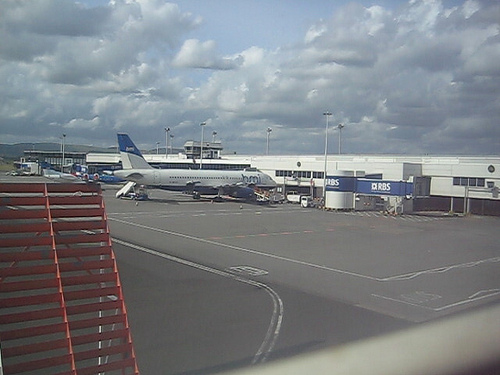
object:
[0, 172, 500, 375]
runway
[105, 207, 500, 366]
lines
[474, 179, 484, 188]
window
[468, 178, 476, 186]
window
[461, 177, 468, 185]
window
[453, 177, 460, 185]
window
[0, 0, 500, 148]
dark clouds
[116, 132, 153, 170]
tail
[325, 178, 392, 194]
logo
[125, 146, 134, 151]
logo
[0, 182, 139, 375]
red steel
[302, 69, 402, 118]
gray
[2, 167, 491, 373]
walkway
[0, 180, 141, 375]
object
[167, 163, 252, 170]
windows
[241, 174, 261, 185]
blue logo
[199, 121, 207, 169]
lightposts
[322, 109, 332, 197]
lightposts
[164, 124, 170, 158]
lightposts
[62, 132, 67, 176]
lightposts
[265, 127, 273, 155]
lightposts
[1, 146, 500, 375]
tarmac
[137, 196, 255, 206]
shadow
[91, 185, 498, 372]
ground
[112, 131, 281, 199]
airplane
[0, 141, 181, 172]
mountains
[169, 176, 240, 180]
windows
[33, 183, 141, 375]
tail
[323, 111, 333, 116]
lights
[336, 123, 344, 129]
lights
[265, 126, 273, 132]
lights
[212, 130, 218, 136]
lights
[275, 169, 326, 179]
windows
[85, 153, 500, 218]
building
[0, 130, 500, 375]
airport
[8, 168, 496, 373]
cement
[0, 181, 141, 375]
structure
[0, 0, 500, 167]
sky